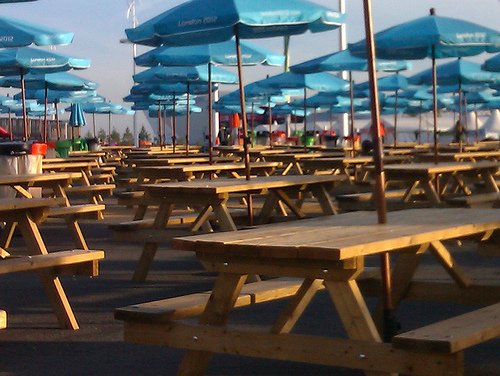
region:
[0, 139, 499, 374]
Tons of wooden picnic benches on cement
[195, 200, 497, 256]
The top of a wooden picnic table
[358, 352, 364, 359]
A metal nail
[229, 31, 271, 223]
The pole of the umbrella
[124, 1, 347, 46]
A blue umbrella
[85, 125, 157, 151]
The tops of trees in the background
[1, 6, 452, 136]
Lines of blue umbrellas over the tables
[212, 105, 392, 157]
People standing behind the benches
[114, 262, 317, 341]
The seat of the table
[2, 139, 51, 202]
A black, orange, and white trash can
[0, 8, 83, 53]
The umbrella is blue.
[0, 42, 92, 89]
The umbrella is blue.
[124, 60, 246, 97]
The umbrella is blue.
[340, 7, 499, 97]
The umbrella is blue.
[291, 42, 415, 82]
The umbrella is blue.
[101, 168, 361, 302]
The table is wood.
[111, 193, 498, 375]
The table is wood.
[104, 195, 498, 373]
The table is vacant.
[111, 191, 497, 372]
The table is unoccupied.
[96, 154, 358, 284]
The table is vacant.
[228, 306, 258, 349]
edge of a wood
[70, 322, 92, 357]
edge of a shade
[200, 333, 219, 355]
aprt of a bolt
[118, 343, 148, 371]
edge of a shade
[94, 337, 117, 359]
edge of a shade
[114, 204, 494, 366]
unpainted wooden picnic table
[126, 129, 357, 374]
row of wooden picnic tables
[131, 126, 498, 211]
large group of empty picnic tables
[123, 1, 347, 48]
blue table umbrella open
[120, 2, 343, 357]
wooden picnic tables with blue umbrellas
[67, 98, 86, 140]
closed blue table umbrella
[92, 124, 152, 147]
small line of pine trees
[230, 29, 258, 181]
vertical wooden pole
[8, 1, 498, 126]
group of open blue umbrellas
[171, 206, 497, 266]
top of wooden picnic table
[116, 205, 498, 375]
table made of wood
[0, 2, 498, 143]
sky is a little hazy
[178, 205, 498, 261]
wood planks on table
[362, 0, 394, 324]
pole of an umbrella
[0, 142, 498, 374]
lots of picnic tables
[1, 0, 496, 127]
a bunch of umbrellas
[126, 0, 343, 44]
the umbrella is blue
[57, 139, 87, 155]
the object is green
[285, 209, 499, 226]
shadow on the table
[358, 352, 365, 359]
metal screw in table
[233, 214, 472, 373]
a wooden picnic bench